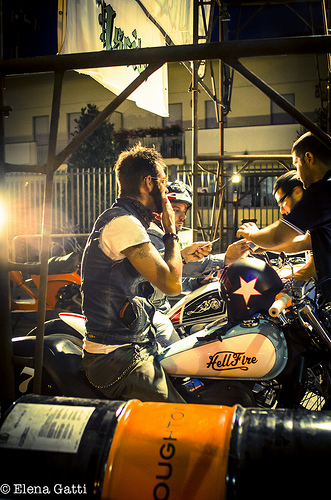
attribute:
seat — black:
[27, 328, 81, 374]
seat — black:
[20, 251, 81, 276]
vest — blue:
[98, 204, 142, 333]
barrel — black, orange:
[1, 392, 329, 498]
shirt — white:
[78, 211, 153, 355]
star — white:
[233, 276, 262, 303]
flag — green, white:
[51, 1, 182, 120]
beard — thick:
[151, 175, 165, 215]